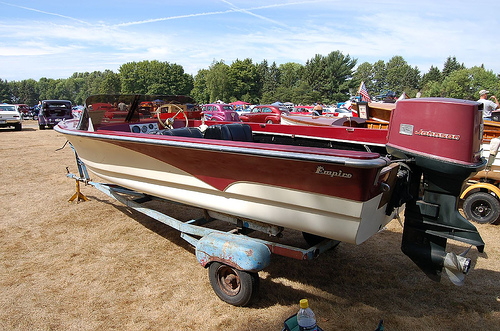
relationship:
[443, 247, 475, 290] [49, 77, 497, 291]
propeller behind boat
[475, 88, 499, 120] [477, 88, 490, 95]
man wearing a cap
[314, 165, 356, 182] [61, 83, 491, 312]
brand name on side of boat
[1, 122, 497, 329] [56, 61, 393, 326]
grass with boat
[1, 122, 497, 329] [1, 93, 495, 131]
grass with cars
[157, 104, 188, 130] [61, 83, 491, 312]
steering wheel on boat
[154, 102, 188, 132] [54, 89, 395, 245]
steering wheel of boat